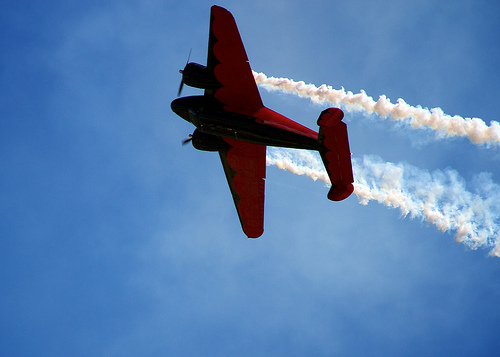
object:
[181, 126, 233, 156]
engine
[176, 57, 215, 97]
engine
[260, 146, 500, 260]
smoke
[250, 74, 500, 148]
smoke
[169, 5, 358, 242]
airplane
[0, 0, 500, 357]
sky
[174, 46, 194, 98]
propeller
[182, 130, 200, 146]
propeller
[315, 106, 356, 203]
tail